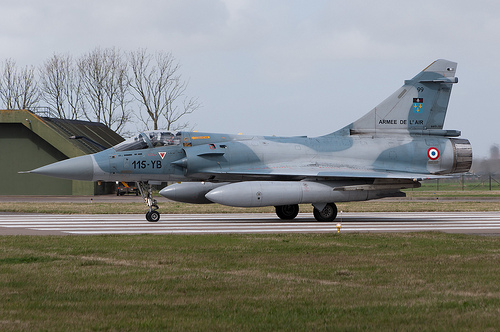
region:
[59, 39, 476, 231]
a gray camouflouge jet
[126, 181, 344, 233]
the landing gear is down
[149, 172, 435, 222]
rockets on the jet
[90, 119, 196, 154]
the cockpit area of the plane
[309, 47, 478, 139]
the tail fin of the jet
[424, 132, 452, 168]
a design on the plane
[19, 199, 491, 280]
a run way in the airfield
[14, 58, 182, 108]
trees in the area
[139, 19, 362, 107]
a cloudy day for flying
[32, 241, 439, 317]
grass on the ground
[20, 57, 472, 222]
Plane on the runway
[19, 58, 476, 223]
Blue and gray plane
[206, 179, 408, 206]
Left engine of plane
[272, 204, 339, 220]
Back wheels of plane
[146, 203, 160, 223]
Two front wheels of plane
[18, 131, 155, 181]
Sharp front of plane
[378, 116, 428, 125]
Black writings on plane's tail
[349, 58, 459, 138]
Tail of a plane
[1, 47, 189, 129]
Bear trees behind building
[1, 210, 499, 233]
White marks on runway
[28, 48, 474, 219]
a jet is on the runway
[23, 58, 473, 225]
the plane is a fighter jet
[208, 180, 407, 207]
a bomb is under the wing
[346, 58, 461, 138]
the tail is painted grey tones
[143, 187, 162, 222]
the landing wheel is down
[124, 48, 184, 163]
the tree is leafless and bare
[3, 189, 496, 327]
the runway is in a grass field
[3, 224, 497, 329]
the grass is green in color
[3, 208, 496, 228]
the runway has lines painted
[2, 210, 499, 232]
the lines are white in color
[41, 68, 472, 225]
a jet on a runway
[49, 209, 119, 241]
white stripes on the runway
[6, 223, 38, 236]
grey concrete of the runway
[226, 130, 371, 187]
blue camouflage paint of the plane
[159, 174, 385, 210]
missiles mounted under the wings of the plane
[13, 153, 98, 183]
the grey nose of the jet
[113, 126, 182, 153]
the glass cockpit cover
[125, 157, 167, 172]
black numbers on the side of the plane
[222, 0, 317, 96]
grey cloudy skies over the airport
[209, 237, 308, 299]
green grass of the ground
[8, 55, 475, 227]
Fighter jet on the tarmac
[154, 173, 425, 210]
Couple of bombs loaded un the wings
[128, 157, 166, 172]
Number tag on the blue body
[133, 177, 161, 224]
Front landing gear on the tarmac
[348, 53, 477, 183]
Tail end of fighter jet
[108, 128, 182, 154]
Clear grass windows of the cockpit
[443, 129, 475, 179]
Exhaust rear of the jet engine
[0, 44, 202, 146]
Group of leafless trees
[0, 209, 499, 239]
Tarmac with white line markings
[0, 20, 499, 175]
Cloudy, misty background sky